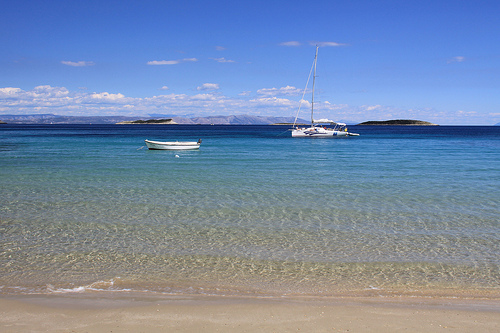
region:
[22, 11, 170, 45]
the sky is blue and clear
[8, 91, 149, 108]
clouds in the sky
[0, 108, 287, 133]
mountains on the horizon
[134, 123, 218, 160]
the boat in the water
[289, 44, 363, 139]
the boat in the water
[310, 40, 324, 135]
the mast on the boat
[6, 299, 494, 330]
sand on the beach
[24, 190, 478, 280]
the water is pristine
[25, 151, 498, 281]
the water is calm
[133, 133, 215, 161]
the boat is white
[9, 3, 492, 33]
the clear blue sky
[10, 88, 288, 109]
the clouds in the sky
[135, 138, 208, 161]
boat in the ocean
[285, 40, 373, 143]
boat in the ocean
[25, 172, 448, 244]
the water is pristine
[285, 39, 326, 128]
the mast on the boat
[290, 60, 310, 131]
line on the mast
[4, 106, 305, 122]
mountains on the horizon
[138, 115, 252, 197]
a boat in water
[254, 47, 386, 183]
a big boat in water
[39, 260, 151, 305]
a small disturbance in water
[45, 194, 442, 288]
riddles in the water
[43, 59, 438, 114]
a white clouds in sky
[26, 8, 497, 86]
a beautiful view of sky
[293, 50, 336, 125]
a long poll on boat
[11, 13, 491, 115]
a clear view of sky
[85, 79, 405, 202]
two boats in water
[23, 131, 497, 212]
a beautiful view of water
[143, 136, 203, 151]
The smaller boat in the water.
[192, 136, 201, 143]
The engine on the back of the smaller boat.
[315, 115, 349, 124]
The white canopy over the larger boat.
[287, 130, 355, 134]
The base of the larger boat in the water.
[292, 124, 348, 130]
The people on the larger boat.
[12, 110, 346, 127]
The mountains in the background.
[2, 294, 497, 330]
The sand area of the beach.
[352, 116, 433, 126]
The island in the background.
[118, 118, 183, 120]
The island in the distance.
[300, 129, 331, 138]
The design on the side of the larger boat.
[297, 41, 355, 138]
The large sail boat.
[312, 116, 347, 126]
The canopy on the sail boat.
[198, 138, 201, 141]
The engine on the back of the smaller boat.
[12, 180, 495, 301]
The water on the shoreline.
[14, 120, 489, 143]
The dark blue water in the distance.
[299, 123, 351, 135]
The people on the larger boat.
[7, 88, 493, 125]
The white clouds in the sky.